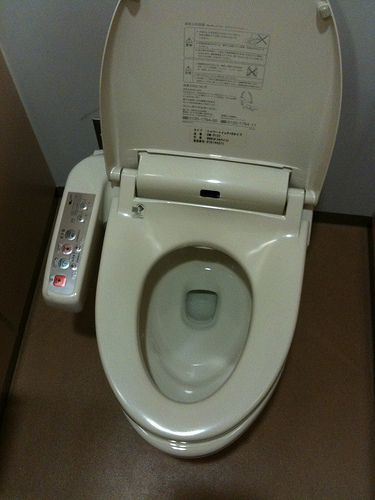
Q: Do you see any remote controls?
A: Yes, there is a remote control.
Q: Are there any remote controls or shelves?
A: Yes, there is a remote control.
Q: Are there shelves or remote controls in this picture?
A: Yes, there is a remote control.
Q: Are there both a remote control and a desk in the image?
A: No, there is a remote control but no desks.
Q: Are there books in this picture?
A: No, there are no books.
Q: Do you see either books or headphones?
A: No, there are no books or headphones.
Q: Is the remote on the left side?
A: Yes, the remote is on the left of the image.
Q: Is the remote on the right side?
A: No, the remote is on the left of the image.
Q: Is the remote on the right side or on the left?
A: The remote is on the left of the image.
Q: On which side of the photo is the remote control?
A: The remote control is on the left of the image.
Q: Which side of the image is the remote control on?
A: The remote control is on the left of the image.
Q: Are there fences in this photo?
A: No, there are no fences.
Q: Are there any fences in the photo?
A: No, there are no fences.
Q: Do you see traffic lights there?
A: No, there are no traffic lights.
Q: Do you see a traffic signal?
A: No, there are no traffic lights.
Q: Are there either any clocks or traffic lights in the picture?
A: No, there are no traffic lights or clocks.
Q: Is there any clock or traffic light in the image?
A: No, there are no traffic lights or clocks.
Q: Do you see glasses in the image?
A: No, there are no glasses.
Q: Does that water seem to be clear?
A: Yes, the water is clear.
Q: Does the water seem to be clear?
A: Yes, the water is clear.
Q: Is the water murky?
A: No, the water is clear.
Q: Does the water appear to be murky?
A: No, the water is clear.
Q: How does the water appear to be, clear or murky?
A: The water is clear.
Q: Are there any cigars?
A: No, there are no cigars.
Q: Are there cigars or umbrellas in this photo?
A: No, there are no cigars or umbrellas.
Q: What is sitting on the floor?
A: The toilet is sitting on the floor.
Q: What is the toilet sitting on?
A: The toilet is sitting on the floor.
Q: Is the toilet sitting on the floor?
A: Yes, the toilet is sitting on the floor.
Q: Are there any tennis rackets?
A: No, there are no tennis rackets.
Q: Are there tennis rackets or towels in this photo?
A: No, there are no tennis rackets or towels.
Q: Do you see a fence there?
A: No, there are no fences.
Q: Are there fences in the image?
A: No, there are no fences.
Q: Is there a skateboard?
A: No, there are no skateboards.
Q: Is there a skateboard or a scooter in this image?
A: No, there are no skateboards or scooters.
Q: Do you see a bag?
A: No, there are no bags.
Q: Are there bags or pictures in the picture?
A: No, there are no bags or pictures.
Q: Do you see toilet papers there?
A: No, there are no toilet papers.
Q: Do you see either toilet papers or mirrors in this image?
A: No, there are no toilet papers or mirrors.